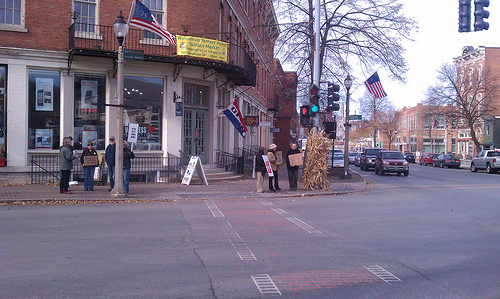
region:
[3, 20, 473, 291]
people standing near street corner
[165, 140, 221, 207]
white sign on sidewalk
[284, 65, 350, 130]
streetlight lit green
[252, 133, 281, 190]
person wearing white sign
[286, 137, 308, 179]
person holding brown sign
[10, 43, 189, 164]
window with multiple posters displayed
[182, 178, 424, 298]
white lines on street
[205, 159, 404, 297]
red marking on street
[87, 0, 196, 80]
flag flying in front of building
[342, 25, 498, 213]
car parked on side of road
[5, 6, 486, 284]
corner of intersection with people and cars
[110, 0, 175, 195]
flag flying on top of lamppost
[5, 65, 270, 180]
storefront with large windows, grey doors and flag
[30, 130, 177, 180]
people standing in front of railing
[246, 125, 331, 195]
people carrying signs by harvest display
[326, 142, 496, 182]
parked and moving cars on street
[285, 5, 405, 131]
pole with traffic sign showing green in front of tree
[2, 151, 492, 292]
gray paved street with patches and faded white and red lines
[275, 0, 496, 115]
bright and clear sky over area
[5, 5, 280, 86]
curved railing above doorway with yellow sign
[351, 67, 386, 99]
flag hanging from flagpole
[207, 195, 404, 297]
crosswalk painted on top of street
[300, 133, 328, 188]
hay bale next to the street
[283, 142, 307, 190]
person holding a brown sign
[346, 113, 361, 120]
street sign attached to lamp post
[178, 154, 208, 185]
white sandwich board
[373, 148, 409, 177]
car on top of street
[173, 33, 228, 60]
yellow banner handing from railing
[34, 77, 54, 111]
poster hanging in window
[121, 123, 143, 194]
person holding white picket sign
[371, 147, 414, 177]
car on the street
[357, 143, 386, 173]
car on the street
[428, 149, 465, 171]
car on the street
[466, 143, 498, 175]
car on the street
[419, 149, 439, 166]
car on the street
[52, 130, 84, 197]
person on the sidewalk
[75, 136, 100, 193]
person on the sidewalk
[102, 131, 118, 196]
person on the sidewalk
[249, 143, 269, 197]
person on the sidewalk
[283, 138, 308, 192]
person on the sidewalk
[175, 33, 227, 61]
Yellow and green sign on brick building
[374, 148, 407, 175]
red car stopped at stop light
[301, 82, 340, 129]
red and green stop light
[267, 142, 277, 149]
bone colored cap person is wearing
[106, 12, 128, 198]
black and silver lamp post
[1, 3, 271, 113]
brick building with lots of windows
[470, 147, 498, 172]
parked silver colored car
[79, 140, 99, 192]
man standing with a protest sign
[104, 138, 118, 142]
sunglasses man is wearing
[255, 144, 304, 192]
three people standing on the side of the street